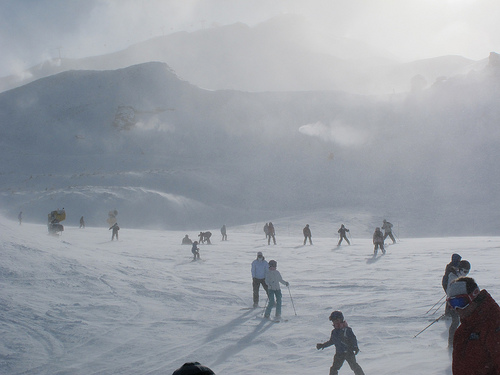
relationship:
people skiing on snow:
[372, 227, 387, 256] [308, 241, 415, 266]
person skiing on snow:
[376, 216, 398, 245] [354, 248, 402, 264]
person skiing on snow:
[337, 224, 351, 246] [318, 241, 378, 282]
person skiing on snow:
[193, 227, 214, 246] [0, 211, 497, 373]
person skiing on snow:
[299, 222, 314, 247] [0, 211, 497, 373]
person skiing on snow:
[336, 220, 351, 244] [0, 211, 497, 373]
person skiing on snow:
[265, 219, 277, 245] [0, 211, 497, 373]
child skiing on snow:
[315, 311, 362, 374] [0, 211, 497, 373]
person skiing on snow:
[258, 261, 284, 323] [247, 301, 312, 339]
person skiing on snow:
[250, 251, 268, 309] [0, 211, 497, 373]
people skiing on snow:
[264, 260, 290, 322] [0, 211, 497, 373]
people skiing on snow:
[372, 227, 387, 256] [0, 211, 497, 373]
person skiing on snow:
[303, 224, 314, 245] [0, 211, 497, 373]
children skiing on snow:
[191, 240, 202, 261] [175, 262, 217, 279]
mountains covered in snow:
[6, 14, 499, 232] [118, 181, 192, 206]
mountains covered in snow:
[6, 14, 499, 232] [129, 108, 174, 135]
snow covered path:
[14, 244, 173, 344] [1, 218, 496, 373]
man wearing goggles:
[434, 272, 498, 373] [443, 290, 476, 313]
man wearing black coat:
[434, 272, 498, 373] [451, 287, 500, 374]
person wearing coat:
[264, 260, 288, 322] [264, 267, 290, 287]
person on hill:
[264, 260, 288, 322] [8, 186, 498, 366]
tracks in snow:
[42, 271, 244, 363] [0, 211, 497, 373]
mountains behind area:
[6, 46, 489, 231] [4, 217, 498, 373]